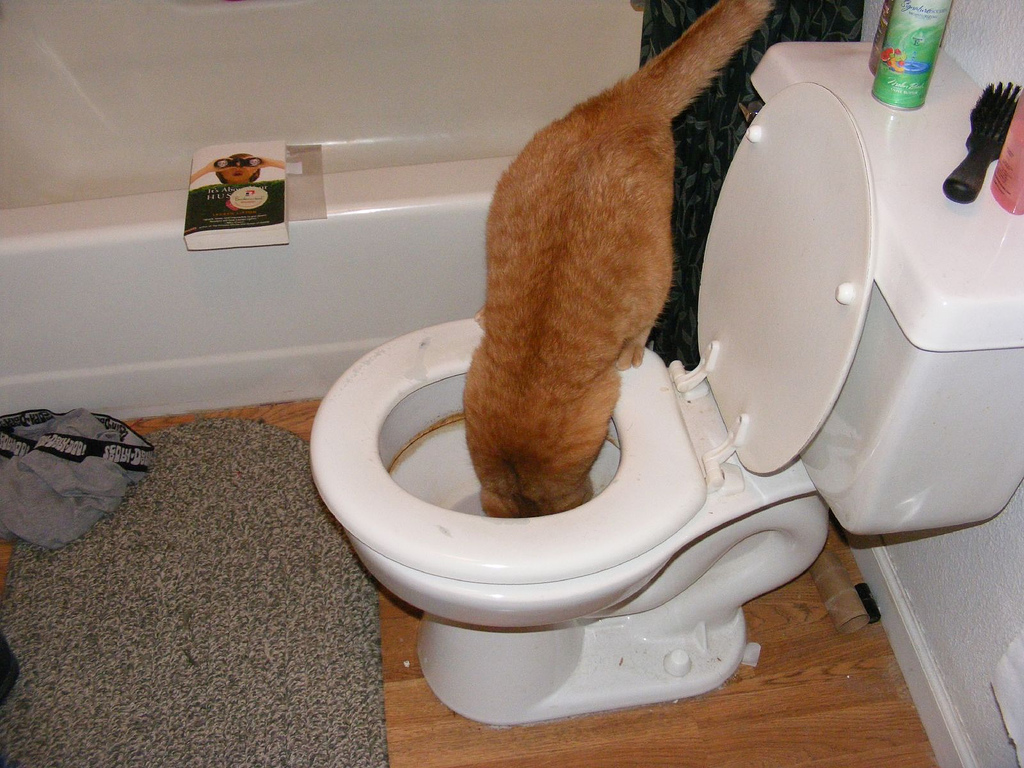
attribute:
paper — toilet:
[984, 628, 1016, 761]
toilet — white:
[501, 61, 806, 706]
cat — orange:
[370, 100, 783, 631]